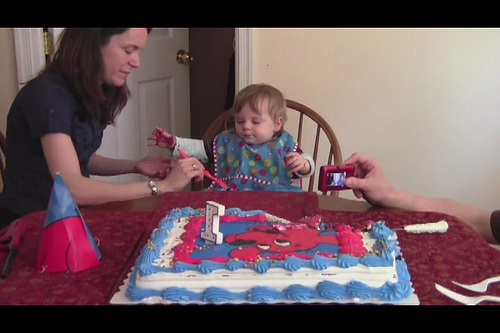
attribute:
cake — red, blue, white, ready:
[174, 192, 393, 295]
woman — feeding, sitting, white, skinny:
[32, 25, 177, 191]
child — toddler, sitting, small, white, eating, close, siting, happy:
[211, 83, 302, 190]